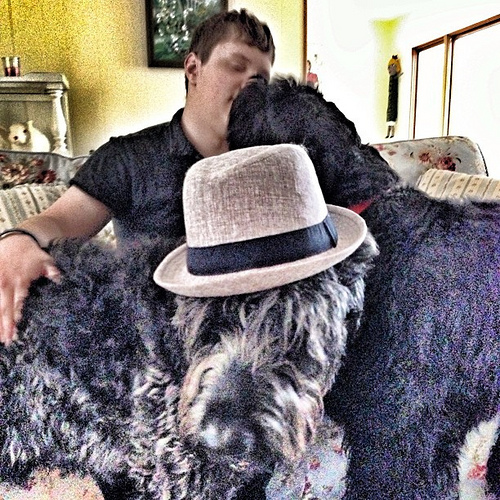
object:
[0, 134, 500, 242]
couch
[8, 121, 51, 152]
bunny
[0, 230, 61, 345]
hand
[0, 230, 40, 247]
band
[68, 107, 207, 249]
shirt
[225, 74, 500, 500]
dog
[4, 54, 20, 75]
candle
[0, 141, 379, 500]
dog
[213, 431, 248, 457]
nose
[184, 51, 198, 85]
ear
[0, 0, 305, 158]
wall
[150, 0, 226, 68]
picture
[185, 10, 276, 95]
brown hair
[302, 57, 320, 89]
poster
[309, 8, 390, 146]
wall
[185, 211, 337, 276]
black ring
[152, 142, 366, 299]
hat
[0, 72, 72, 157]
shelf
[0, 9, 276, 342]
guy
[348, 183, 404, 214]
collar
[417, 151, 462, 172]
floral pattern